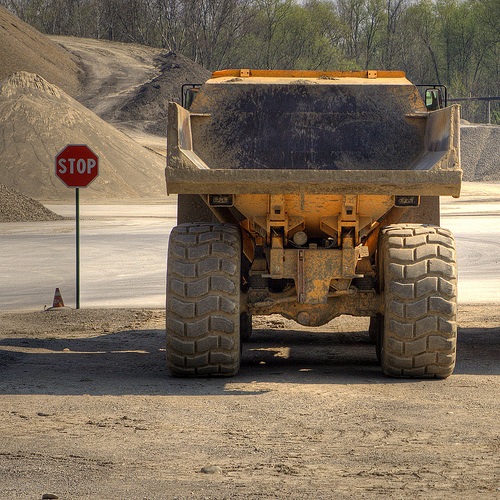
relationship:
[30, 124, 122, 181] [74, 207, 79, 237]
sign on a pole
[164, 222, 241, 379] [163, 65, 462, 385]
rear wheel on tractor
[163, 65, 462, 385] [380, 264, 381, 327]
tractor has a right wheel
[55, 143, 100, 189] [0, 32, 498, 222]
sign on field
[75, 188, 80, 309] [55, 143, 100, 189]
pole holding sign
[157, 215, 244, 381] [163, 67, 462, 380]
rear wheel of a tractor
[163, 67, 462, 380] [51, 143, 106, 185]
tractor by stop sign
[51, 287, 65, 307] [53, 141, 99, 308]
cone by stop sign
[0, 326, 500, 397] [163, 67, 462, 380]
shadow of a tractor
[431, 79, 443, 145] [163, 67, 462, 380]
mirror on tractor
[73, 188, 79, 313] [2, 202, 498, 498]
pole in ground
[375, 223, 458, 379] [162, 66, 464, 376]
right wheel of truck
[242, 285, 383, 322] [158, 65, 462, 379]
rear axle of machine